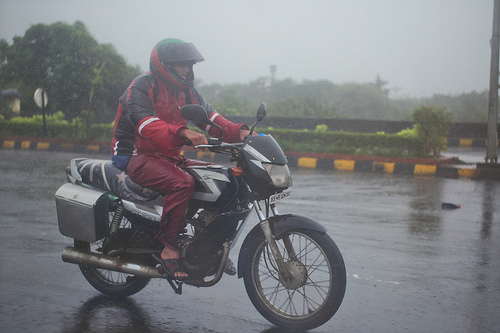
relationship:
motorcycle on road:
[53, 104, 348, 330] [1, 146, 499, 331]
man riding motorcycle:
[109, 38, 259, 283] [53, 104, 348, 330]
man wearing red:
[109, 38, 259, 283] [110, 72, 261, 270]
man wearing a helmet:
[109, 38, 259, 283] [148, 37, 209, 90]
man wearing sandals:
[109, 38, 259, 283] [155, 246, 240, 288]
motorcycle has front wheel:
[53, 104, 348, 330] [238, 214, 350, 330]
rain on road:
[354, 174, 484, 224] [1, 146, 499, 331]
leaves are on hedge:
[2, 111, 442, 156] [0, 105, 446, 164]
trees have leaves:
[0, 22, 151, 125] [28, 36, 124, 123]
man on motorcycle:
[109, 38, 259, 283] [53, 104, 348, 330]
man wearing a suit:
[109, 38, 259, 283] [114, 74, 249, 254]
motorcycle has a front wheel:
[53, 104, 348, 330] [239, 212, 353, 330]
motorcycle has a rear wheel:
[53, 104, 348, 330] [67, 209, 161, 295]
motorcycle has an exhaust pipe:
[53, 104, 348, 330] [58, 242, 173, 282]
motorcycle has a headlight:
[53, 104, 348, 330] [255, 162, 296, 193]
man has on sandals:
[109, 38, 259, 283] [155, 246, 240, 288]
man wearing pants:
[109, 38, 259, 283] [115, 151, 230, 256]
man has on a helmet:
[109, 38, 259, 283] [148, 37, 209, 90]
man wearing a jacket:
[109, 38, 259, 283] [112, 75, 258, 172]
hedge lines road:
[0, 105, 446, 164] [1, 146, 499, 331]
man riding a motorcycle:
[109, 38, 259, 283] [53, 104, 348, 330]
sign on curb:
[31, 81, 49, 113] [1, 129, 500, 178]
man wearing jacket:
[109, 38, 259, 283] [112, 75, 258, 172]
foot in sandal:
[160, 243, 187, 279] [150, 247, 194, 282]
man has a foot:
[109, 38, 259, 283] [160, 243, 187, 279]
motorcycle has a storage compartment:
[53, 104, 348, 330] [49, 184, 120, 245]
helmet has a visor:
[148, 37, 209, 90] [161, 42, 206, 69]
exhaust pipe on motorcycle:
[58, 242, 173, 282] [53, 104, 348, 330]